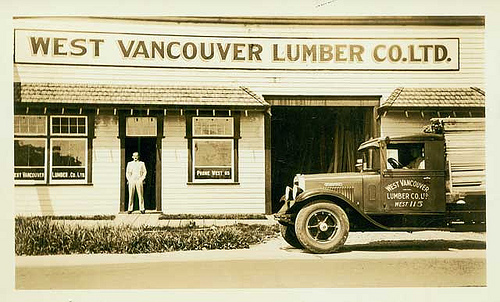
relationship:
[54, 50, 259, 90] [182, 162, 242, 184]
letters on a sign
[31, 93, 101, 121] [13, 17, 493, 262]
light siding on building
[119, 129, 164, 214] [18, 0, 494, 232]
doorway of building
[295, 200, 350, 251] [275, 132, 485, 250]
tire on truck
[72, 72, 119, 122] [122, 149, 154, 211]
shingled awning on building above man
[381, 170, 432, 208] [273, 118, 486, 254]
door driver side of lorry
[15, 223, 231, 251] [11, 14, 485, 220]
plants near building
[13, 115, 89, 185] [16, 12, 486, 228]
windows of house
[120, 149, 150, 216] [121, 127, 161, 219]
man standing in doorway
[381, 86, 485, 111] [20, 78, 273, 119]
tiles roof on roof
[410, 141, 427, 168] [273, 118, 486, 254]
person driving lorry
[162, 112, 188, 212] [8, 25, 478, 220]
clap boards on wall